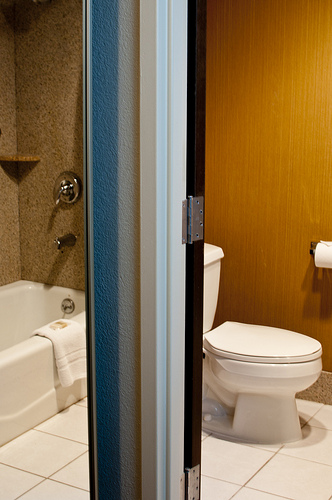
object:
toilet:
[202, 241, 320, 443]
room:
[200, 5, 331, 497]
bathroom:
[0, 3, 332, 500]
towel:
[32, 317, 86, 391]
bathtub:
[0, 277, 87, 449]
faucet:
[53, 232, 76, 254]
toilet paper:
[305, 233, 331, 283]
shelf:
[0, 150, 40, 168]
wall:
[0, 0, 81, 284]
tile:
[2, 391, 331, 497]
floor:
[2, 393, 331, 500]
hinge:
[182, 195, 203, 245]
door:
[182, 1, 206, 500]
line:
[93, 6, 121, 496]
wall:
[92, 0, 183, 499]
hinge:
[183, 464, 200, 497]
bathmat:
[29, 319, 86, 390]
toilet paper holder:
[305, 237, 331, 269]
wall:
[202, 1, 327, 409]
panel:
[202, 0, 332, 372]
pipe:
[54, 232, 77, 253]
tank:
[203, 238, 225, 330]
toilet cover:
[203, 320, 321, 366]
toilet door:
[184, 0, 203, 500]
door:
[87, 0, 144, 500]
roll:
[308, 241, 331, 281]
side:
[1, 332, 89, 438]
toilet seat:
[208, 317, 324, 365]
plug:
[61, 297, 74, 315]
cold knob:
[54, 171, 82, 206]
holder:
[307, 240, 331, 276]